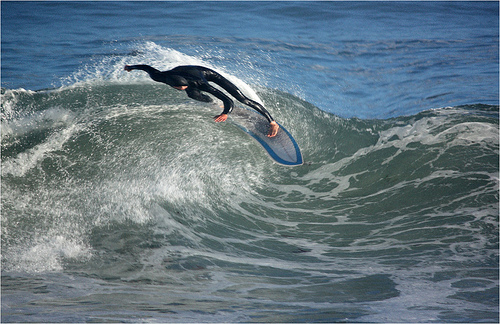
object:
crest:
[0, 66, 136, 104]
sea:
[0, 225, 500, 324]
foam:
[371, 112, 491, 145]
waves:
[92, 38, 280, 139]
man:
[124, 64, 280, 138]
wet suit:
[131, 64, 275, 123]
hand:
[212, 113, 227, 123]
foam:
[365, 273, 449, 320]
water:
[121, 0, 288, 43]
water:
[0, 249, 500, 324]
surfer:
[124, 65, 279, 138]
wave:
[0, 39, 500, 273]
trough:
[0, 104, 348, 269]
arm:
[125, 64, 158, 80]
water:
[332, 30, 481, 97]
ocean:
[0, 0, 500, 322]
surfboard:
[219, 103, 303, 165]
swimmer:
[124, 64, 280, 138]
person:
[123, 64, 279, 138]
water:
[3, 2, 97, 58]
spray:
[136, 41, 172, 59]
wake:
[246, 81, 281, 104]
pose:
[121, 64, 281, 140]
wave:
[0, 38, 227, 139]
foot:
[265, 120, 279, 137]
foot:
[214, 102, 224, 108]